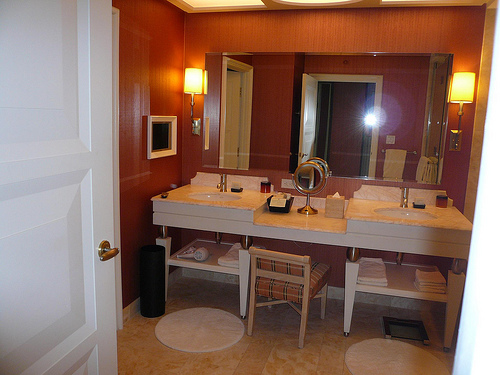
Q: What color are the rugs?
A: White.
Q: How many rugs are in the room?
A: Two.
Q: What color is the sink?
A: White.